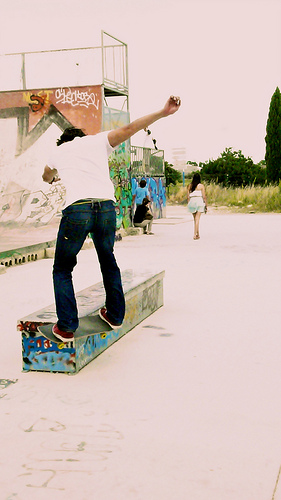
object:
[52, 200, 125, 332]
jeans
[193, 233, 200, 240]
feet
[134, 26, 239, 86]
clouds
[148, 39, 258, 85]
roof window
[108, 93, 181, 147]
arm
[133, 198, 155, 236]
man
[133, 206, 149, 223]
shirt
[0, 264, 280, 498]
ground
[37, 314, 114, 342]
skateboard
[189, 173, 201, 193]
hair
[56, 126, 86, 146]
hair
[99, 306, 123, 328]
foot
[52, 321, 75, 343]
foot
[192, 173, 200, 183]
head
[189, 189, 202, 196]
shirt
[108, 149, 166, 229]
grafitti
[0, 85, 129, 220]
wall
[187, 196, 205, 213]
skirt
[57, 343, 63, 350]
wheel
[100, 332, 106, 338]
wheel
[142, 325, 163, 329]
stain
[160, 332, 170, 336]
stain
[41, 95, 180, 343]
person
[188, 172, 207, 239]
person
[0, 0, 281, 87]
sky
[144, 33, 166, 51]
white cloud